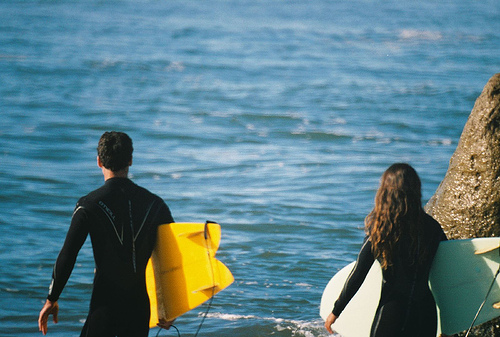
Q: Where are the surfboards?
A: Under the people's arms.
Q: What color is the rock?
A: Brown.